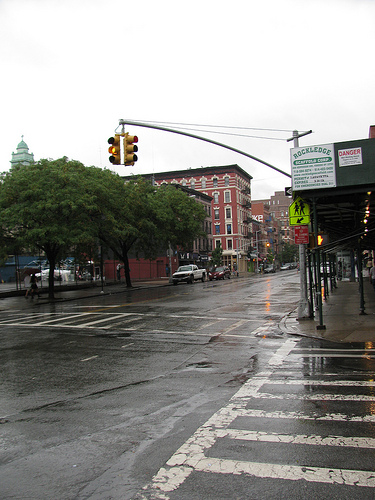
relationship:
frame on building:
[224, 189, 232, 203] [77, 162, 255, 284]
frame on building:
[224, 204, 233, 222] [77, 162, 255, 284]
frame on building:
[225, 222, 233, 234] [77, 162, 255, 284]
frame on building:
[226, 237, 233, 251] [77, 162, 255, 284]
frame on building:
[214, 238, 222, 253] [77, 162, 255, 284]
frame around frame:
[223, 186, 233, 206] [224, 189, 232, 203]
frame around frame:
[223, 203, 234, 220] [224, 204, 233, 222]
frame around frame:
[223, 220, 233, 238] [225, 222, 233, 234]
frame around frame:
[224, 235, 235, 251] [226, 237, 233, 251]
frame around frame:
[212, 238, 224, 255] [214, 238, 222, 253]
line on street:
[265, 376, 374, 391] [4, 265, 374, 499]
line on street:
[239, 408, 374, 426] [4, 265, 374, 499]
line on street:
[219, 427, 374, 452] [4, 265, 374, 499]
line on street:
[194, 456, 374, 488] [4, 265, 374, 499]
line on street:
[144, 334, 298, 498] [4, 265, 374, 499]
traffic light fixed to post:
[121, 133, 137, 169] [115, 117, 296, 185]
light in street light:
[104, 144, 121, 156] [107, 132, 123, 168]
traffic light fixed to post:
[107, 132, 123, 168] [115, 117, 296, 185]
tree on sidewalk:
[2, 153, 127, 304] [1, 275, 175, 315]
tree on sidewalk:
[83, 174, 151, 293] [1, 275, 175, 315]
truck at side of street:
[169, 264, 209, 288] [4, 265, 374, 499]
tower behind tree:
[8, 132, 36, 177] [2, 153, 127, 304]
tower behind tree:
[8, 132, 36, 177] [83, 174, 151, 293]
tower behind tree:
[8, 132, 36, 177] [136, 183, 207, 286]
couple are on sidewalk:
[21, 270, 43, 302] [1, 275, 175, 315]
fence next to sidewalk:
[0, 253, 108, 301] [1, 275, 175, 315]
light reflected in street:
[263, 240, 273, 250] [4, 265, 374, 499]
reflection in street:
[263, 276, 275, 316] [4, 265, 374, 499]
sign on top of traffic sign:
[288, 194, 313, 227] [292, 224, 312, 247]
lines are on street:
[78, 338, 149, 368] [4, 265, 374, 499]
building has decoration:
[77, 162, 255, 284] [149, 173, 250, 195]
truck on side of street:
[169, 264, 209, 288] [4, 265, 374, 499]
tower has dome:
[8, 132, 36, 177] [16, 140, 30, 152]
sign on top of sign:
[289, 141, 338, 193] [288, 194, 313, 227]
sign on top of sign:
[288, 194, 313, 227] [292, 224, 312, 247]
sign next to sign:
[289, 141, 338, 193] [336, 146, 365, 167]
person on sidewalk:
[163, 262, 172, 283] [1, 275, 175, 315]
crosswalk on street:
[2, 305, 289, 342] [4, 265, 374, 499]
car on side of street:
[206, 262, 233, 282] [4, 265, 374, 499]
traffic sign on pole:
[292, 224, 312, 247] [291, 132, 311, 322]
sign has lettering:
[289, 141, 338, 193] [291, 146, 336, 191]